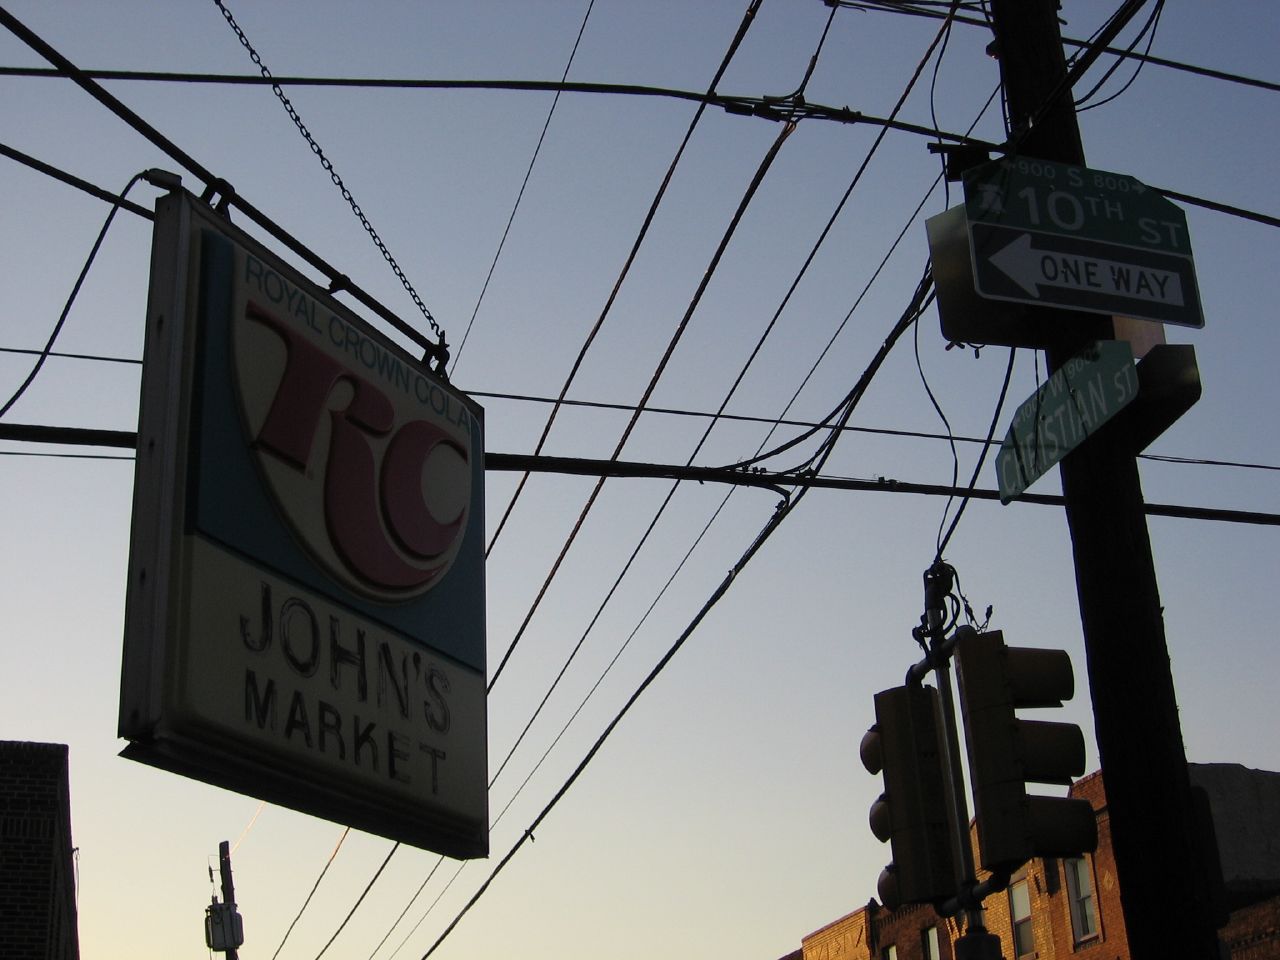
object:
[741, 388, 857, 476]
bend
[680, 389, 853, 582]
cables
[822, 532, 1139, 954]
traffic signal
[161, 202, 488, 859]
sign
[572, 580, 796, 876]
sky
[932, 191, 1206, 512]
street signs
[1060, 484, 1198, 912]
pole